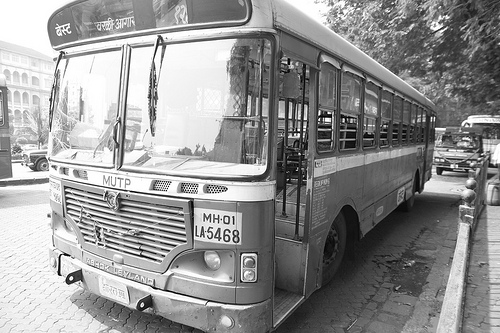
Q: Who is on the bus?
A: Not one person.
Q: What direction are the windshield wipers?
A: Down.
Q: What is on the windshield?
A: Wipers.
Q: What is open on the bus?
A: The door.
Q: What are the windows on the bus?
A: Open.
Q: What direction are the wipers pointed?
A: Down.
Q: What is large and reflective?
A: The windshield.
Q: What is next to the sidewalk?
A: A bus.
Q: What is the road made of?
A: Cobble stone.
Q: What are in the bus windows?
A: Bara.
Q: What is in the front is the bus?
A: Radiator cover.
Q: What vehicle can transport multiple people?
A: The bus.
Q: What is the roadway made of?
A: Brick pavers.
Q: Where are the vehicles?
A: Behind the bus.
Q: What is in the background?
A: Trees.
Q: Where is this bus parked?
A: Near a barrier.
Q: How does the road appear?
A: Cracked.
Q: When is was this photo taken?
A: Daytime.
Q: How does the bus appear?
A: Old.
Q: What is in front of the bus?
A: A license plate.